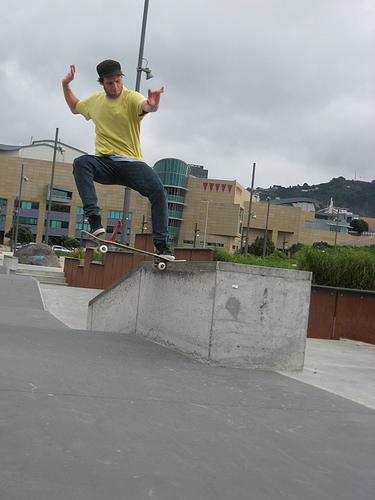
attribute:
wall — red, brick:
[62, 232, 363, 343]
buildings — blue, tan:
[3, 124, 362, 265]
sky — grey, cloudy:
[7, 4, 362, 182]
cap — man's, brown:
[94, 57, 123, 80]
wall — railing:
[85, 261, 314, 373]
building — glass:
[151, 155, 189, 258]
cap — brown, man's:
[94, 59, 124, 82]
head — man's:
[94, 57, 123, 95]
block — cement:
[84, 255, 314, 370]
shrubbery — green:
[210, 240, 370, 289]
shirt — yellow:
[74, 89, 149, 158]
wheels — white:
[91, 242, 107, 255]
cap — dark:
[96, 57, 124, 77]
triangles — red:
[199, 180, 233, 192]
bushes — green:
[214, 245, 363, 290]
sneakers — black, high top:
[86, 213, 176, 263]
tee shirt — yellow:
[77, 88, 145, 160]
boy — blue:
[63, 63, 174, 255]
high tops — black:
[88, 215, 176, 260]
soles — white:
[90, 224, 173, 260]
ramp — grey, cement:
[84, 236, 315, 373]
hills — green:
[244, 173, 372, 215]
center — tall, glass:
[149, 154, 193, 244]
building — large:
[2, 155, 368, 243]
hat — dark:
[92, 56, 126, 83]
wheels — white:
[90, 242, 173, 271]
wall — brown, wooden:
[61, 242, 372, 345]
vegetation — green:
[217, 237, 369, 288]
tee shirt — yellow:
[73, 84, 145, 165]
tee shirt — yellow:
[71, 86, 150, 161]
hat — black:
[94, 57, 127, 81]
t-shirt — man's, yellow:
[75, 86, 145, 158]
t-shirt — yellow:
[73, 84, 143, 165]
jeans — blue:
[69, 151, 173, 241]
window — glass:
[18, 201, 26, 209]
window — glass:
[25, 198, 31, 207]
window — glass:
[104, 207, 111, 217]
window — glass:
[110, 209, 116, 216]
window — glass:
[54, 220, 61, 228]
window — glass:
[28, 216, 36, 225]